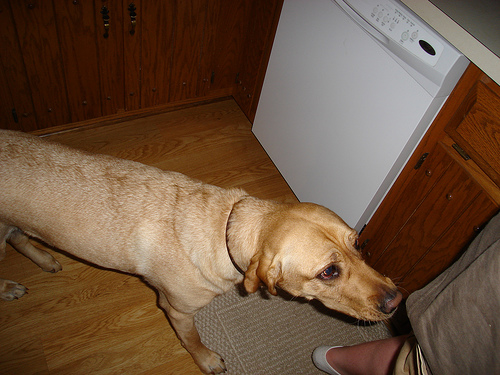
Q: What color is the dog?
A: The dog is tan.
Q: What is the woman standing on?
A: A rug.